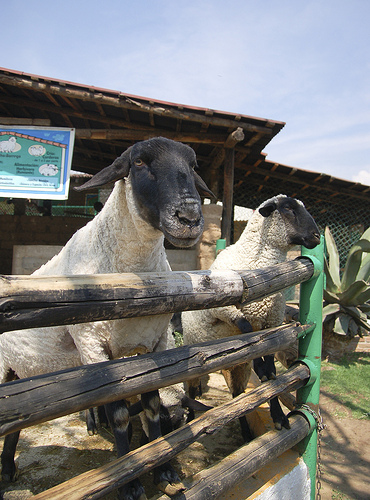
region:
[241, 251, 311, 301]
weathered wooden fence post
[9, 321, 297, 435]
weathered wooden fence post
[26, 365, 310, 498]
weathered wooden fence post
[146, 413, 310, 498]
weathered wooden fence post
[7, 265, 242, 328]
weathered wooden fence post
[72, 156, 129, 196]
black colored sheep ear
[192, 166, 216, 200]
black colored sheep ear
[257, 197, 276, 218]
black colored sheep ear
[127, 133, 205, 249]
black colored sheep head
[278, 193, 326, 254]
black colored sheep head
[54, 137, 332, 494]
sheep looking over wooden fence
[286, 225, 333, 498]
metal post for wooden fence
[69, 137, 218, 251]
black face on a white sheep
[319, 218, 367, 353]
green plant with large leaves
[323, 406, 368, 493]
shadow of tree on ground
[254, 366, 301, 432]
hooves of sheep supported by wood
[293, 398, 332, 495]
metal chain on bar holder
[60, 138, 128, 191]
floppy right ear of sheep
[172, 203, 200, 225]
nostrils on gray nose of sheep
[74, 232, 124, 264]
pretty white wool on neck of sheep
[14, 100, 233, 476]
this is a sheep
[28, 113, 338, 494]
two sheeps standing together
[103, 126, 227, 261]
black head of sheep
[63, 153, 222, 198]
black ears on sheep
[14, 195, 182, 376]
tan fur on sheep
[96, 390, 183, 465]
black legs on sheep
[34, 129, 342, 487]
sheeps leaning on a fence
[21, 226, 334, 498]
the fence is wooden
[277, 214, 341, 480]
green post on fence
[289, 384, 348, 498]
chain hanging off of post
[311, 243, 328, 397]
The pole is green.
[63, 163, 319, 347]
Sheep behind the pen.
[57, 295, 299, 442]
Pen is made of wood.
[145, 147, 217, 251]
The sheep face is black.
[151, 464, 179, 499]
The sheep foot on pole.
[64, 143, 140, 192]
The sheep ear is black.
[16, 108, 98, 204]
A sign is posted by the roof.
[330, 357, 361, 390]
The grass on the side is green.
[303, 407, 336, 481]
Chain hanging from the pole.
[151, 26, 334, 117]
The sky is clear and blue.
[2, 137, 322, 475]
two sheep in a pen.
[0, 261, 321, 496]
wooden fence in front of sheep.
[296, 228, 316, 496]
the fence post is green.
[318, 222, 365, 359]
plant with large leaves.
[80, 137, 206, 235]
the sheep has a black face.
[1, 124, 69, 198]
sign in behind the sheep.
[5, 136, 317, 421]
two sheep are leaning against the wood railing.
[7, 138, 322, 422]
the sheep are white.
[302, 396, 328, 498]
chain hanging from green post.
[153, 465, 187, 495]
sheep has hoof on railing.